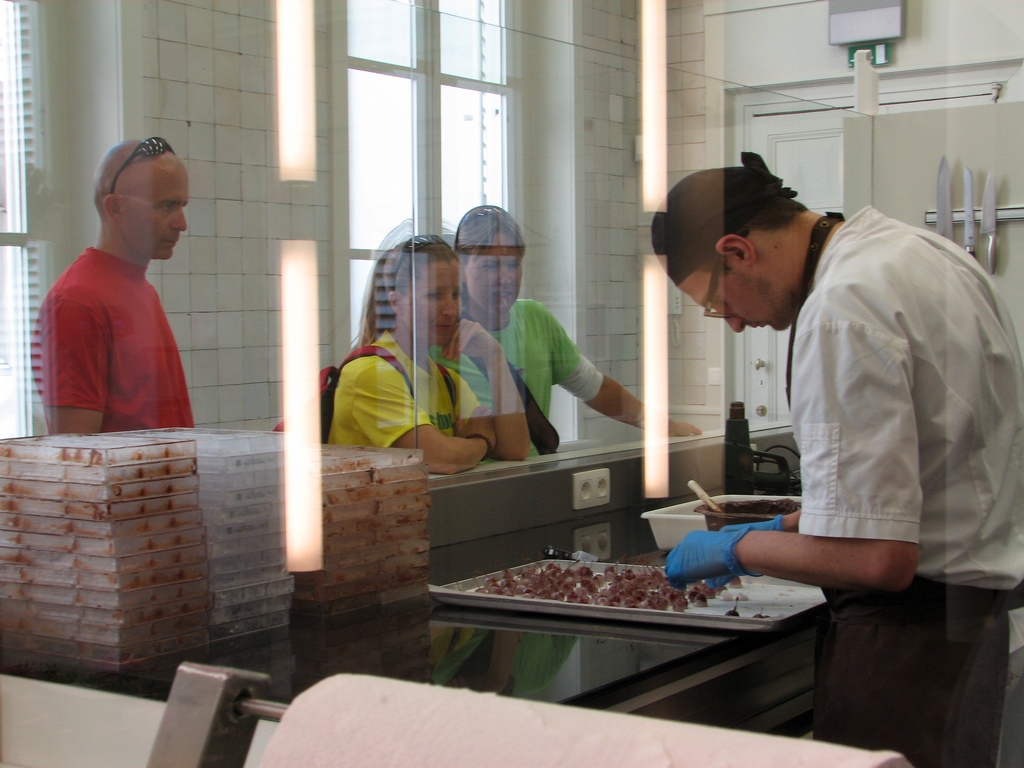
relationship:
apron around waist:
[748, 209, 1021, 672] [804, 568, 1021, 616]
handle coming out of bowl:
[683, 477, 718, 512] [644, 493, 809, 563]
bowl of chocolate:
[644, 493, 809, 563] [698, 491, 805, 524]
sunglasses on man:
[684, 268, 733, 335] [648, 152, 1004, 760]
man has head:
[648, 152, 1004, 760] [92, 138, 200, 269]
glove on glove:
[655, 522, 767, 583] [665, 514, 785, 590]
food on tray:
[475, 563, 738, 612] [450, 541, 831, 643]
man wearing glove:
[648, 152, 1004, 760] [665, 514, 785, 590]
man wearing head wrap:
[648, 152, 1004, 760] [643, 154, 830, 276]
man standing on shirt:
[29, 130, 208, 435] [33, 244, 189, 428]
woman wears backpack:
[320, 236, 537, 475] [302, 335, 464, 452]